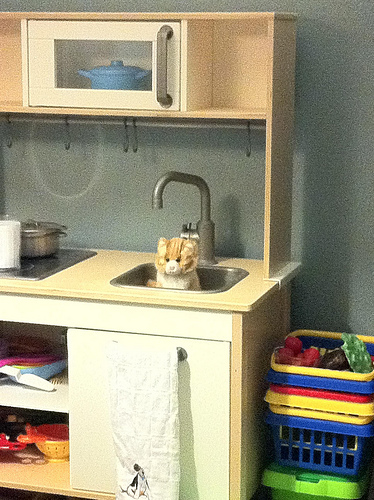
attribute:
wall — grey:
[324, 260, 343, 291]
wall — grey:
[325, 13, 358, 42]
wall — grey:
[353, 223, 364, 328]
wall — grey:
[55, 167, 120, 211]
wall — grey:
[11, 157, 28, 211]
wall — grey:
[304, 142, 367, 156]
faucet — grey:
[145, 169, 234, 228]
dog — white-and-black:
[115, 459, 154, 499]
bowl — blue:
[73, 72, 157, 90]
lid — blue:
[83, 56, 148, 73]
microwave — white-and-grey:
[15, 18, 195, 113]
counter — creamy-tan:
[72, 249, 110, 295]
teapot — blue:
[83, 55, 161, 93]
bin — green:
[257, 464, 367, 498]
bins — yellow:
[264, 387, 373, 430]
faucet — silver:
[151, 161, 224, 262]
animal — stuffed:
[143, 228, 212, 287]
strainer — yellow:
[20, 424, 73, 465]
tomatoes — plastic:
[280, 333, 320, 371]